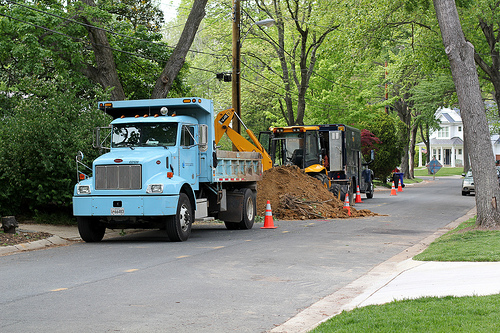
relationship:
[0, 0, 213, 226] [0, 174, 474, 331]
trees line street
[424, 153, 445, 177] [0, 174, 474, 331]
sign at end of street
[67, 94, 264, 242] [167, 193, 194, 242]
dump truck has tire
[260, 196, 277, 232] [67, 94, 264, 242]
cone next to dump truck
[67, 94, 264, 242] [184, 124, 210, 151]
dump truck has mirror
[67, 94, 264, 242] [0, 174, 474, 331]
dump truck parked on street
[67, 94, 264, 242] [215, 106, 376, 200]
dump truck parked behind road machine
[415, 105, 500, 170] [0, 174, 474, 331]
house at end of street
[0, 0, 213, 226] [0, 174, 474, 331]
trees lining street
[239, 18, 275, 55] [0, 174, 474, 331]
street lamp over street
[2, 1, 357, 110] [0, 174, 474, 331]
lines extending across street